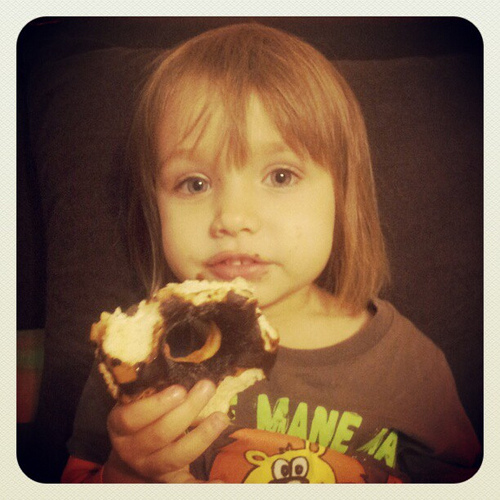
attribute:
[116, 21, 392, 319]
hair — brown, short, blonde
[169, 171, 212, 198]
eyes — blue, big, brown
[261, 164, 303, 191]
eyes — blue, big, brown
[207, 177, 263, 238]
nose — cute, little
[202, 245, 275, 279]
mouth — cute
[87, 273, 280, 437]
donut — chocolate frosting, big, chocolate, iced, brown, half eaten, slightly eaten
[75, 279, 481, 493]
pullover — brown, gray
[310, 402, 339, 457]
n — yellow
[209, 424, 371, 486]
lion — orange, yellow, animal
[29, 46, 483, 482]
chair — brown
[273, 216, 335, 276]
cheeks — chubby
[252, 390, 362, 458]
mane — green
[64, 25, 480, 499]
girl — beautiful, little, eating